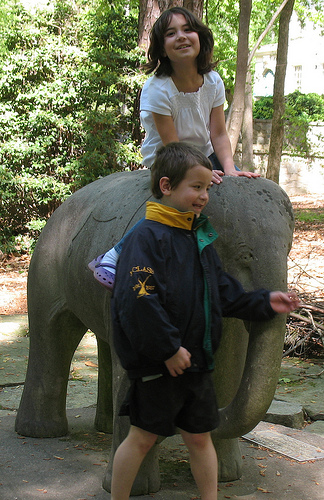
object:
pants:
[113, 147, 242, 257]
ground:
[0, 208, 324, 500]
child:
[110, 142, 301, 498]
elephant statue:
[15, 169, 294, 495]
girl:
[87, 6, 260, 288]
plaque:
[242, 430, 324, 462]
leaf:
[52, 453, 64, 461]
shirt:
[139, 71, 226, 169]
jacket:
[110, 200, 272, 379]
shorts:
[118, 361, 219, 436]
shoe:
[87, 252, 116, 290]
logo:
[128, 265, 155, 299]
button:
[207, 232, 212, 239]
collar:
[145, 200, 194, 230]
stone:
[265, 404, 302, 429]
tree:
[0, 0, 142, 261]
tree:
[0, 1, 138, 265]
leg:
[110, 369, 172, 498]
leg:
[176, 369, 218, 500]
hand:
[166, 346, 193, 378]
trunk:
[211, 261, 289, 440]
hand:
[225, 169, 262, 179]